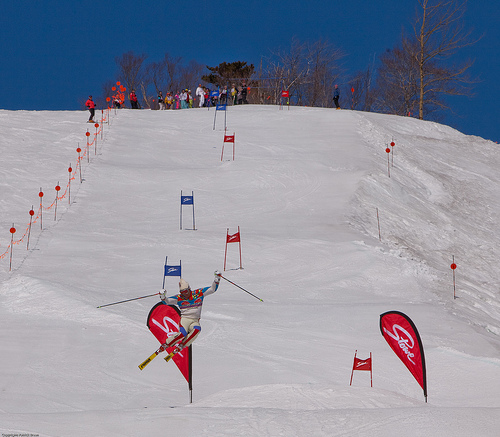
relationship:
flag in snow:
[334, 343, 394, 419] [294, 227, 372, 323]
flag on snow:
[334, 343, 394, 419] [294, 227, 372, 323]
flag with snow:
[334, 343, 394, 419] [294, 227, 372, 323]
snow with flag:
[294, 227, 372, 323] [334, 343, 394, 419]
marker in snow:
[135, 190, 207, 214] [294, 227, 372, 323]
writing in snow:
[321, 150, 356, 214] [294, 227, 372, 323]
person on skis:
[158, 279, 212, 318] [133, 329, 208, 374]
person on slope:
[155, 279, 220, 356] [146, 167, 268, 368]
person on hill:
[158, 279, 212, 318] [117, 50, 274, 182]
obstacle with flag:
[200, 210, 276, 286] [334, 343, 394, 419]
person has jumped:
[155, 279, 220, 356] [125, 203, 238, 355]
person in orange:
[158, 279, 212, 318] [107, 79, 144, 105]